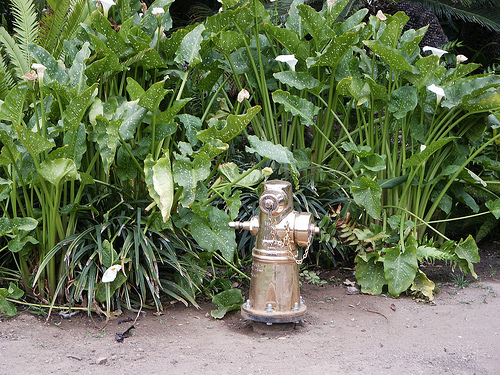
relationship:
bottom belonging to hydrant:
[236, 297, 307, 336] [225, 178, 321, 339]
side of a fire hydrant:
[256, 186, 308, 311] [226, 179, 321, 337]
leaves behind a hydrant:
[4, 4, 486, 314] [225, 178, 321, 339]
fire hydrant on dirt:
[222, 175, 321, 337] [2, 275, 492, 370]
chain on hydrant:
[263, 206, 315, 266] [225, 178, 321, 339]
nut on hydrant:
[257, 194, 277, 214] [225, 178, 321, 339]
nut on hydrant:
[225, 217, 241, 229] [225, 178, 321, 339]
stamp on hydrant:
[257, 232, 286, 254] [222, 175, 325, 335]